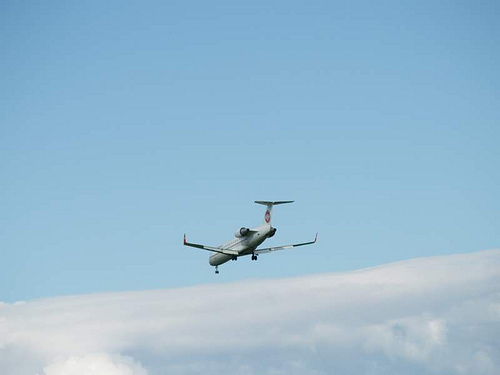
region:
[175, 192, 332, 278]
Plane in the air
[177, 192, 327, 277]
Plane is in the air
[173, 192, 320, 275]
Airplane in the air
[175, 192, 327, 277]
Airplane is in the air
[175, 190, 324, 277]
Plane flying in the air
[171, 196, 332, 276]
Plane is flying in the air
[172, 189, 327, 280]
Airplane flying in the air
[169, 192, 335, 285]
Airplane is flying in the air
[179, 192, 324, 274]
Airplane up in the air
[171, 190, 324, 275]
Airplane is up in the air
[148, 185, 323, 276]
plane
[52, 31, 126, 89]
white clouds in blue sky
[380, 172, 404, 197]
white clouds in blue sky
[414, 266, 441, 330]
white clouds in blue sky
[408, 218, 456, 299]
white clouds in blue sky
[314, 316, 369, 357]
white clouds in blue sky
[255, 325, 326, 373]
white clouds in blue sky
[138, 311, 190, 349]
white clouds in blue sky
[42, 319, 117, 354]
white clouds in blue sky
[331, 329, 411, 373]
white clouds in blue sky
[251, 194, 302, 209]
Gray tail on plane.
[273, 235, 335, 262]
Large wing on side of plane.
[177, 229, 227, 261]
Large wing on side of plane.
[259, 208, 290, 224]
Red circle on tail of plane.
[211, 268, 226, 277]
Black wheel on plane.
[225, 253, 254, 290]
Landing gear is down on plane.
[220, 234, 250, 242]
Windows along side of plane.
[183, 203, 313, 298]
Airplane flying in sky.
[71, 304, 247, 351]
White clouds under plane.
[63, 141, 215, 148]
Sky is blue and clear.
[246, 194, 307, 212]
TAIL OF JET IN SKY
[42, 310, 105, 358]
PUFFY CLOUDS IN SKY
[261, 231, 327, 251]
WING OF JET PLANE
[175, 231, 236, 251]
WING OF JET PLANE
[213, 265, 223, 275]
WHEEL OF JET PLANE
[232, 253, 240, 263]
WHEEL OF JET PLANE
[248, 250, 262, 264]
WHEEL OF JET PLANE IN SKY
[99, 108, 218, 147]
LIGHT BLUE COLOR OF SKY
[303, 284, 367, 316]
PUFFY WHITE CLOUDS IN SKY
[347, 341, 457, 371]
PUFFY WHITE CLOUDS IN SKY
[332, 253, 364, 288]
white clouds in blue sky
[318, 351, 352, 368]
white clouds in blue sky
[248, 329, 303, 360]
white clouds in blue sky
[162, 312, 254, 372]
white clouds in blue sky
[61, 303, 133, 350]
white clouds in blue sky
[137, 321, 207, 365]
white clouds in blue sky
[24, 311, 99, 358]
white clouds in blue sky